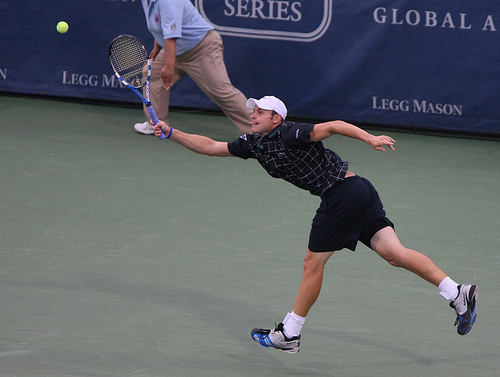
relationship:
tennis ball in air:
[57, 21, 69, 35] [12, 38, 111, 149]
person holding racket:
[151, 96, 485, 358] [105, 33, 167, 140]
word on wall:
[371, 8, 475, 35] [300, 23, 493, 117]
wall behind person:
[300, 23, 493, 117] [151, 96, 485, 358]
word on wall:
[221, 0, 306, 24] [300, 23, 493, 117]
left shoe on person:
[247, 326, 304, 356] [151, 96, 485, 358]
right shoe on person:
[450, 282, 480, 337] [151, 96, 485, 358]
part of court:
[63, 251, 104, 300] [14, 143, 491, 376]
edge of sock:
[290, 309, 312, 325] [283, 313, 304, 342]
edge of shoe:
[279, 329, 301, 341] [245, 327, 302, 356]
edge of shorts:
[306, 242, 366, 254] [308, 171, 399, 256]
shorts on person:
[308, 171, 399, 256] [151, 96, 485, 358]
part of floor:
[63, 251, 104, 300] [6, 175, 348, 372]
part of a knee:
[305, 260, 309, 263] [302, 251, 328, 275]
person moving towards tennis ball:
[151, 96, 485, 358] [57, 21, 69, 35]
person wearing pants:
[139, 4, 256, 141] [145, 33, 243, 133]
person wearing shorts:
[151, 96, 485, 358] [308, 171, 399, 256]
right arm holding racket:
[145, 120, 258, 163] [105, 33, 167, 140]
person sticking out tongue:
[151, 96, 485, 358] [249, 120, 259, 126]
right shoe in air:
[450, 282, 480, 337] [12, 38, 111, 149]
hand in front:
[146, 113, 177, 142] [152, 106, 185, 146]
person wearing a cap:
[151, 96, 485, 358] [244, 94, 295, 128]